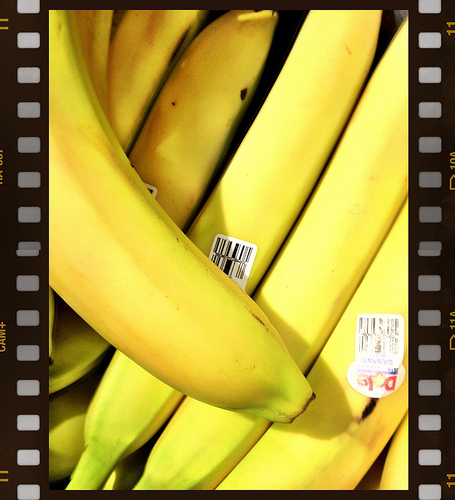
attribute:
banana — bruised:
[48, 20, 343, 439]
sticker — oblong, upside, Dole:
[341, 298, 404, 404]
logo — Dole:
[347, 356, 406, 398]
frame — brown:
[0, 0, 49, 498]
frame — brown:
[408, 0, 454, 499]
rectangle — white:
[16, 31, 40, 47]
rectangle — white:
[16, 100, 41, 118]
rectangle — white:
[16, 169, 41, 187]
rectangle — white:
[417, 66, 443, 84]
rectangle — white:
[418, 134, 442, 152]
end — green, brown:
[258, 378, 314, 422]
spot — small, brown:
[239, 87, 248, 101]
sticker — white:
[323, 310, 411, 405]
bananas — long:
[45, 44, 404, 487]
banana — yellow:
[54, 15, 323, 429]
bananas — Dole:
[51, 11, 409, 490]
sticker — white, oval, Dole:
[347, 362, 405, 399]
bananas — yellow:
[45, 11, 318, 421]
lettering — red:
[359, 373, 397, 394]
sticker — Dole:
[347, 358, 404, 395]